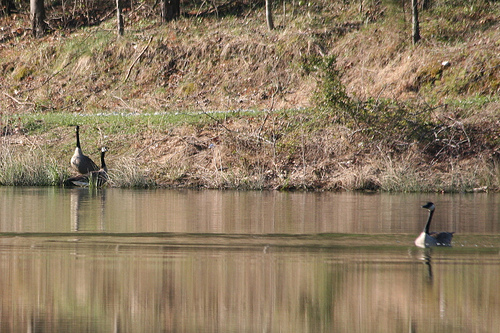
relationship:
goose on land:
[68, 122, 101, 172] [1, 30, 497, 190]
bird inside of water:
[401, 194, 461, 254] [16, 178, 496, 317]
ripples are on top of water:
[130, 230, 274, 259] [16, 178, 496, 317]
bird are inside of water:
[413, 201, 455, 249] [16, 178, 496, 317]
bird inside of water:
[413, 201, 455, 249] [16, 178, 496, 317]